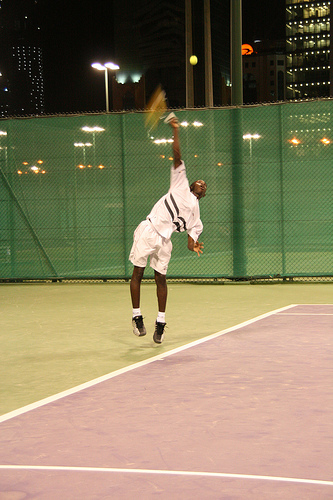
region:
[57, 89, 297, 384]
a man playing tennis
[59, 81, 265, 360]
a man on a court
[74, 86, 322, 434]
a man on a tennis court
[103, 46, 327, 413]
a tennis player on a tennis court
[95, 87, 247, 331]
a man jumping in the air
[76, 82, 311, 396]
a tennis player jumping in the air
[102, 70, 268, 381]
a man swinging a racket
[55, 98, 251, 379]
a man swinging a tennis racket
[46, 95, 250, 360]
a man in a white uniform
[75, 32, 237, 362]
a man in a white tennis uniform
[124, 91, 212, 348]
the tennis player is in the middle of a swing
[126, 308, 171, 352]
his feet are off the ground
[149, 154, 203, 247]
his shirt is white and black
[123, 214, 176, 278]
his shorts are white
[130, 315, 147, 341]
his sneakers are black and white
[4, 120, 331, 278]
a green mesh fence divides the courts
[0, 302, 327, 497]
the court is made with red clay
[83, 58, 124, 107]
the lights above the court are on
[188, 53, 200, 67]
the moon in the sky is yellow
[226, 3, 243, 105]
a metal pole is on the other side of the fence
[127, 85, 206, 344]
man swinging tennis racket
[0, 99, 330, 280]
green canvas over fence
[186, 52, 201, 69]
tennis ball in mid air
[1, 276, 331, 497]
green and brown floor of tennis court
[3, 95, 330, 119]
spike on top of chain link fence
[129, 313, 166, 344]
pair of black and white sneakers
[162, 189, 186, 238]
black stripes on white shirt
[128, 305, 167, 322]
pair of white ankle socks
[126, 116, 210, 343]
man jumping off ground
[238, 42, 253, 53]
bright orange moon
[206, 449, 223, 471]
part of a court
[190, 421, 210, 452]
part of a court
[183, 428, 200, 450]
part of a court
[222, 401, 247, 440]
part of a court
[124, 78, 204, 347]
man jumping to hit tennis ball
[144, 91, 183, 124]
tennis racket being swung by man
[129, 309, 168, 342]
black and white shoes of tennis player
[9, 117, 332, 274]
green mesh on fenceline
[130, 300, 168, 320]
white socks of tennis player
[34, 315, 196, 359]
shadow of tennis player on court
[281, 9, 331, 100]
bulding on right side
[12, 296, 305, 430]
white baseline of tennis court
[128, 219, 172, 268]
white shorts of tennis player